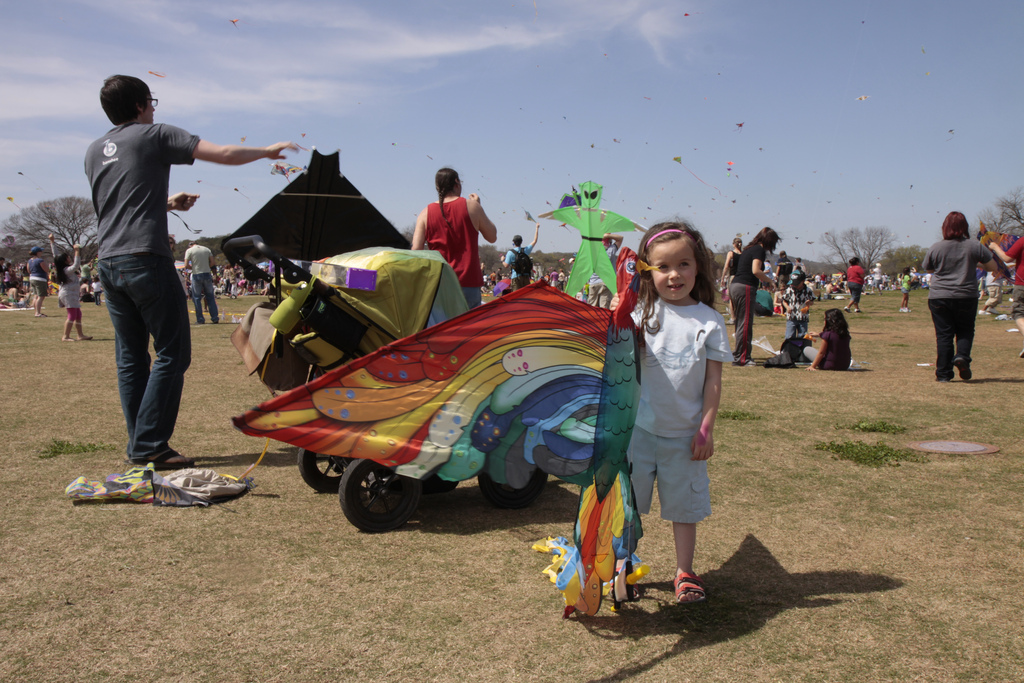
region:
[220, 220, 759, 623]
The girl is holding a colorful kite.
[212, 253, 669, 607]
The kite is colorful.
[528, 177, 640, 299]
The kite is green.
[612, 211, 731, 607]
The girl is wearing a white shirt.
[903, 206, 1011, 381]
The woman is wearing a gray shirt.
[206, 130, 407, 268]
The kite is black.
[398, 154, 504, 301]
The woman is wearing a red shirt.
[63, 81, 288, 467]
The man is wearing a gray shirt.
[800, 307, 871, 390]
The woman is sitting down on the grass.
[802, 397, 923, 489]
The patch of grass is very green.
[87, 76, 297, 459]
person is in a park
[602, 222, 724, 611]
person is in a park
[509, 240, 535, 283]
person is in a park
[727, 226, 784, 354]
person is in a park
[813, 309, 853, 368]
person is in a park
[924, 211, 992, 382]
person is in a park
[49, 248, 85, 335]
person is in a park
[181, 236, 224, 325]
person is in a park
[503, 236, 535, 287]
person is in a park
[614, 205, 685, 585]
a person standing in a field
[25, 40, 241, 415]
a person standing in a field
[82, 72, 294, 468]
man in a grey shirt flying a green kite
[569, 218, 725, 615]
a child in pink sandals holding a kite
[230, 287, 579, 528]
a cart with black wheels and a kite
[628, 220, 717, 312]
girl in a white t shirt with a pink hair band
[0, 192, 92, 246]
a tree in the distance with no leaves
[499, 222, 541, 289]
man in a blue shirt with a black back pack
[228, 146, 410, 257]
a large black bat kite in the background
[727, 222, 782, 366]
a lady in a black shirt and grey and red striped warm up pants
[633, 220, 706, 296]
head of a girl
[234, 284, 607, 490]
a rainbow color kite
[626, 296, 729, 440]
the shirt is white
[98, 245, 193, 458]
the pants are blue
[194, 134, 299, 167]
arm of a man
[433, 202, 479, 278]
the shirt is red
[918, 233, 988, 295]
the shirt is gray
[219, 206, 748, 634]
Little girl holding a kite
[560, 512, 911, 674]
Shadow on the grass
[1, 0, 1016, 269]
Clouds are in the sky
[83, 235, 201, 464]
A pair of jeans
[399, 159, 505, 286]
Person reading a red tank top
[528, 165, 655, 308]
A kite is green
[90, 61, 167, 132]
Black hair on guy's head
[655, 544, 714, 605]
A pink colored sandal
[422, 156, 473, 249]
Brown hair in a long braid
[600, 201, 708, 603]
A person is standing up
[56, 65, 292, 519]
A person is standing up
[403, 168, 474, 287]
A person is standing up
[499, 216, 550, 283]
A person is standing up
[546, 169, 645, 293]
A kite in the sky.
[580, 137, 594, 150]
A kite in the sky.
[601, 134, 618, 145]
A kite in the sky.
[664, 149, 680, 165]
A kite in the sky.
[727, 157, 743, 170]
A kite in the sky.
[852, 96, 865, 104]
A kite in the sky.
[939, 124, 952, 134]
A kite in the sky.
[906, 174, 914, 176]
A kite in the sky.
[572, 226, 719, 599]
A person is standing up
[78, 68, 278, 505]
A person is standing up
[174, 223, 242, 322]
A person is standing up